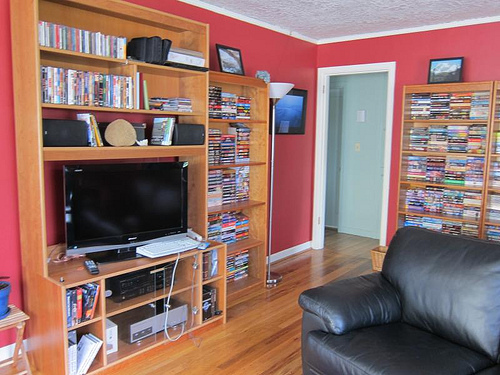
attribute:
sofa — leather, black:
[294, 203, 499, 374]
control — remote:
[81, 260, 99, 280]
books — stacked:
[34, 16, 207, 115]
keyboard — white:
[131, 234, 204, 265]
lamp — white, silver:
[260, 72, 298, 301]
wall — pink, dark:
[0, 0, 500, 350]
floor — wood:
[4, 221, 499, 374]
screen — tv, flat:
[61, 160, 195, 257]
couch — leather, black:
[295, 214, 499, 374]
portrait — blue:
[270, 82, 308, 136]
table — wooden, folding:
[0, 297, 32, 375]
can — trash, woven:
[369, 242, 392, 273]